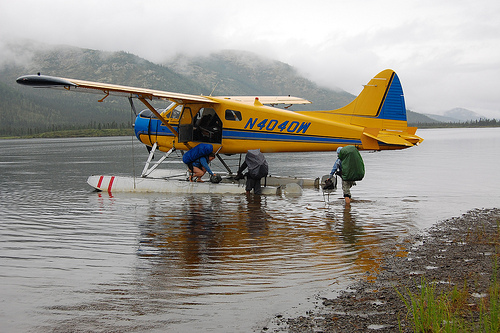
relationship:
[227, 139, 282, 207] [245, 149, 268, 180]
man with backpack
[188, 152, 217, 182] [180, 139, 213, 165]
people with ruck sack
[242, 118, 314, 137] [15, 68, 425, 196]
text on plane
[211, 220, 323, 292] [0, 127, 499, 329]
ripples on lake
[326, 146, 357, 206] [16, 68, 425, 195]
guy boarding water plane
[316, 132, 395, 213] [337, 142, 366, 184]
guy carrying luggage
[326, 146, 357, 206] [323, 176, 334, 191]
guy carrying luggage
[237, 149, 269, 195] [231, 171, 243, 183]
man carrying luggage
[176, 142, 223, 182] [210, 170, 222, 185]
people carrying luggage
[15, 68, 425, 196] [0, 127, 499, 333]
plane standing in lake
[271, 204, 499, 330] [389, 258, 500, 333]
dirt with some grass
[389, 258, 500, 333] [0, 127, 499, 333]
grass near lake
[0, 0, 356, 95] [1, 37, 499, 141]
fog appearing near hills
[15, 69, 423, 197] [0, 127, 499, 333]
plane making ripples in lake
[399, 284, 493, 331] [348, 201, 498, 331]
grass on shore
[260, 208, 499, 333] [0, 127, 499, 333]
dirt on lake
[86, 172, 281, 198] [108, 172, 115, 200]
pontoon with stripe